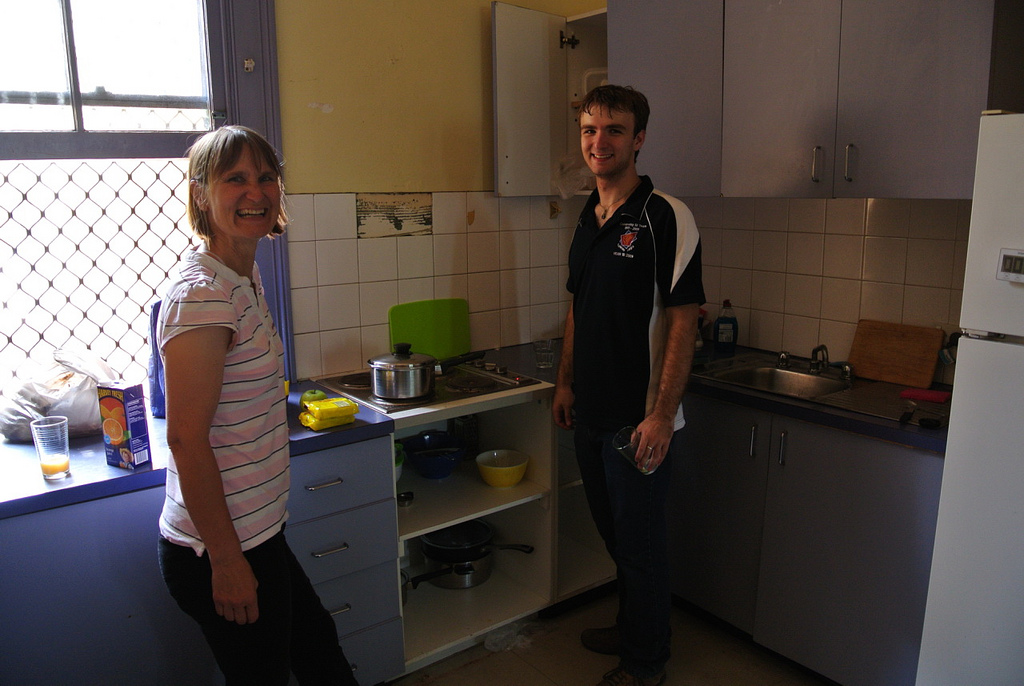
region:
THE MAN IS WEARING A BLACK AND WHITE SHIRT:
[520, 165, 705, 457]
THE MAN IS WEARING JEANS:
[564, 412, 683, 679]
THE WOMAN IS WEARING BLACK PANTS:
[144, 503, 360, 678]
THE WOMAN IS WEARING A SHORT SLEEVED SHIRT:
[138, 239, 306, 559]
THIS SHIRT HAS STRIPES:
[125, 251, 302, 569]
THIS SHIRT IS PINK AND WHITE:
[138, 223, 316, 571]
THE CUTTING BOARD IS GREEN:
[377, 285, 473, 383]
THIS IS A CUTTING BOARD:
[368, 294, 477, 387]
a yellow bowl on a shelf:
[479, 438, 534, 493]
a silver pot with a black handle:
[361, 324, 507, 402]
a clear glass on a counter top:
[30, 406, 65, 482]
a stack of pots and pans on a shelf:
[412, 516, 533, 605]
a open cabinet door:
[482, 3, 597, 200]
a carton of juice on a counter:
[95, 357, 156, 482]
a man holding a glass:
[613, 402, 670, 479]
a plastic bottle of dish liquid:
[703, 291, 741, 364]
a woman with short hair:
[180, 130, 291, 244]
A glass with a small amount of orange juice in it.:
[27, 412, 72, 485]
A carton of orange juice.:
[95, 379, 152, 474]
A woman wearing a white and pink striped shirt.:
[153, 126, 356, 683]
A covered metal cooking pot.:
[365, 338, 439, 400]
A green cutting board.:
[386, 293, 476, 360]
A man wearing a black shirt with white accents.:
[547, 82, 710, 683]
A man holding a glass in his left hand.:
[550, 80, 709, 682]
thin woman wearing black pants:
[157, 129, 351, 681]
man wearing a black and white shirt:
[555, 83, 705, 682]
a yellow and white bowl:
[478, 447, 532, 487]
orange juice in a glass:
[29, 415, 72, 482]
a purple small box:
[95, 375, 150, 473]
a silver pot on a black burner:
[315, 336, 549, 431]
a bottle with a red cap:
[710, 295, 743, 359]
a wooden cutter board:
[841, 314, 946, 388]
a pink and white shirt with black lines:
[156, 248, 290, 558]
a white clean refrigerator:
[917, 106, 1020, 680]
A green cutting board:
[377, 292, 501, 359]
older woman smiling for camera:
[151, 120, 355, 683]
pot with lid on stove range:
[369, 341, 439, 402]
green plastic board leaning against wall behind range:
[386, 294, 478, 364]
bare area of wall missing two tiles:
[350, 187, 440, 242]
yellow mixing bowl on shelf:
[470, 445, 531, 490]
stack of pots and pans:
[400, 530, 546, 591]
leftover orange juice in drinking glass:
[29, 413, 75, 483]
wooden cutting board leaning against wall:
[844, 315, 950, 396]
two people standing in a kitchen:
[143, 83, 719, 682]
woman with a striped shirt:
[143, 119, 362, 677]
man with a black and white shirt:
[556, 76, 716, 665]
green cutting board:
[386, 291, 476, 367]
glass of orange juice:
[29, 410, 75, 486]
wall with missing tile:
[284, 186, 509, 376]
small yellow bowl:
[468, 435, 536, 494]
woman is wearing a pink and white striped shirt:
[148, 117, 357, 683]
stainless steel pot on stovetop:
[315, 337, 546, 421]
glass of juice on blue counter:
[2, 385, 394, 519]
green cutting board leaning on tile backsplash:
[292, 193, 970, 389]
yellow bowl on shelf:
[378, 420, 544, 548]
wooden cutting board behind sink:
[730, 306, 953, 405]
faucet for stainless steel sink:
[720, 337, 861, 407]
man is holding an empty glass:
[546, 82, 706, 674]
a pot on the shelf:
[491, 429, 540, 475]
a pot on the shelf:
[415, 423, 447, 463]